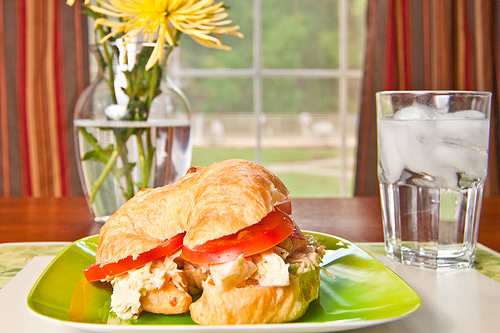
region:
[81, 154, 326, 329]
A CROISSANT SANDWICH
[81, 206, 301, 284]
TWO SLICES OF TOMATOE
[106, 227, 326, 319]
CHICKEN ON A SANDWICH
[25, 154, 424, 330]
A SANDWICH ON A GREEN PLATE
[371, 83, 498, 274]
A GLASS OF ICE WATER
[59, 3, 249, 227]
A VASE WITH YELLOW FLOWERS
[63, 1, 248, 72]
YELLOW FLOWERS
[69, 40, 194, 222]
A CLEAR FLOWER VASE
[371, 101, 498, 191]
ICE CUBES IN A GLASS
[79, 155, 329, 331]
A CHICKEN AND TOMATO SANDWICH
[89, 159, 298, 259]
The top of a golden brown and flakey croissant.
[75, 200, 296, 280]
Red sliced tomatoes.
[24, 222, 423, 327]
A green square plate with rounded edges.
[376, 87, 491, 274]
A clear glass.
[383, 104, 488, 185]
Ice cubes floating on top of liquid in a glass.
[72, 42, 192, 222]
A clear flower vase.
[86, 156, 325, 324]
A croissant sandwich.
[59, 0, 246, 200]
Yellow flowers with long stems.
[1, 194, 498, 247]
A wooden table.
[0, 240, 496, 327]
A placemat on a table.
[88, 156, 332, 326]
chicken salad sandwich on a split croissant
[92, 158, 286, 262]
top half of a split croissant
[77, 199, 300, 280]
sliced red tomatoes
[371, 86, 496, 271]
glass of ice water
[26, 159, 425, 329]
croissant chicken salad sandwich on green plate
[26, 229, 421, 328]
green lunch sized plate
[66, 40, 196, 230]
glass flower vase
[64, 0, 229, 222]
glass vase filled with water and flowers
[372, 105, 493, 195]
ice floating in water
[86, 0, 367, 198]
window to the backyard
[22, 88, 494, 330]
a tasty looking lunch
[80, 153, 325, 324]
a tuna sandwich on a crescent roll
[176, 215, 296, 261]
a thick slice of red tomato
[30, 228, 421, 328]
a lime colored plate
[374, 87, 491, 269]
a glass of ice water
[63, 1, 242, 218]
yellow flowers in a glass vase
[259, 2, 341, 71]
a glass window pane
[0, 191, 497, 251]
a brown wooden table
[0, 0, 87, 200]
a striped patterned drapery panel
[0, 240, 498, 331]
a plastic place mat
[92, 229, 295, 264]
The slices of tomato on the croissant.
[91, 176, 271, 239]
The top croissant bun.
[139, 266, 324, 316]
The bottom croissant bun.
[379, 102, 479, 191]
The ice in the glass.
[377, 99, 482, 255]
The water in the glass.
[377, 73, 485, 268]
The glass on the table.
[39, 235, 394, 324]
The green plate the sandwich is on.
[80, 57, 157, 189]
The stems of the flowers in the vase.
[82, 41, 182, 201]
The glass vase on the table.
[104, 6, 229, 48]
The yellow flowers in the vase.